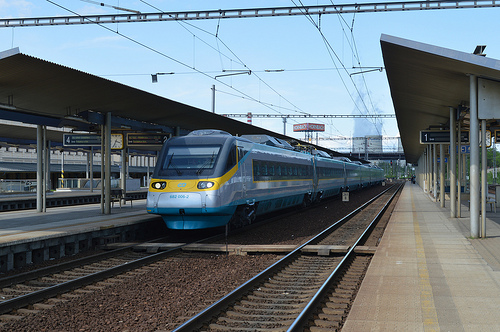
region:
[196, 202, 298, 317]
The rail road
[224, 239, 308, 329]
The rail road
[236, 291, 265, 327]
The rail road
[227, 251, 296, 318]
The rail road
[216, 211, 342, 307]
The rail road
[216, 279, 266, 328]
The rail road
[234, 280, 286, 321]
The rail road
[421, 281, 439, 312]
the line is yellow and black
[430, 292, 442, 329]
the line is yellow and black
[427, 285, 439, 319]
the line is yellow and black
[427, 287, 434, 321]
the line is yellow and black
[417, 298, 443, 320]
the line is yellow and black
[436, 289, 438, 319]
the line is yellow and black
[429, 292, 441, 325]
the line is yellow and black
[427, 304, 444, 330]
the line is yellow and black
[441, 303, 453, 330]
the line is yellow and black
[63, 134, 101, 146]
Sign with the number 4 on it.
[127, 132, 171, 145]
Sign with the number 2 on it.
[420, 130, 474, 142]
Sign with the number 1 on it.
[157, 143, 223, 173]
Front window shield of train.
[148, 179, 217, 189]
Two headlights on train.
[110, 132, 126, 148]
Clock between platform 2 and 4.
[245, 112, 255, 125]
Red and white striped structure in background.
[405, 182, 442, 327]
Yellow walkway stripe on platform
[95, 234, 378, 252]
Metal track beam in front of train.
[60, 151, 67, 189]
Metal pole with black and yellow stripes on its bottom half.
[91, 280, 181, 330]
Rocks between tracks.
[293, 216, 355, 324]
The railway tracks.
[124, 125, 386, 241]
A train in the station.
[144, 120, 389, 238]
A train on the tracks.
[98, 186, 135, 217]
An empty station bench.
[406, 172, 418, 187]
People waiting on the platform.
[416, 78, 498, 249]
Columns for the roof.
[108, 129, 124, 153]
A clock on the column.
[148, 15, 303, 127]
Wires hang over head.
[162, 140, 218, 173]
Windshelind and the wipers.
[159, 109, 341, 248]
A train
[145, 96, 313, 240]
A train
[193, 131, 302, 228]
A train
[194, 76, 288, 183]
A train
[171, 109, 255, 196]
A train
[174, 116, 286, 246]
A train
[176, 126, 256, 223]
A train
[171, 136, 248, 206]
A train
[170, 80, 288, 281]
A train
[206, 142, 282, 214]
A train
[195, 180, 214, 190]
Headlights of a train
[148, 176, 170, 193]
Headlights of a train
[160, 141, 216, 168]
Window of a train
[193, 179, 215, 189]
Headlights of a long train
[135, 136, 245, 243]
front of yellow and white train